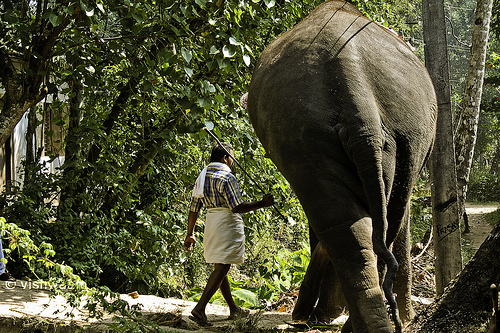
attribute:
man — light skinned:
[181, 142, 276, 326]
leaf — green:
[221, 44, 237, 61]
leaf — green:
[243, 53, 250, 66]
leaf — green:
[216, 55, 232, 70]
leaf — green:
[229, 37, 241, 46]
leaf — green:
[243, 42, 253, 54]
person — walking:
[183, 139, 276, 323]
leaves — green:
[143, 53, 215, 137]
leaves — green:
[110, 3, 252, 80]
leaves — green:
[106, 127, 183, 284]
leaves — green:
[3, 3, 136, 60]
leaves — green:
[235, 146, 276, 197]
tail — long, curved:
[362, 149, 404, 331]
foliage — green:
[53, 2, 195, 291]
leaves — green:
[200, 78, 214, 95]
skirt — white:
[203, 208, 248, 265]